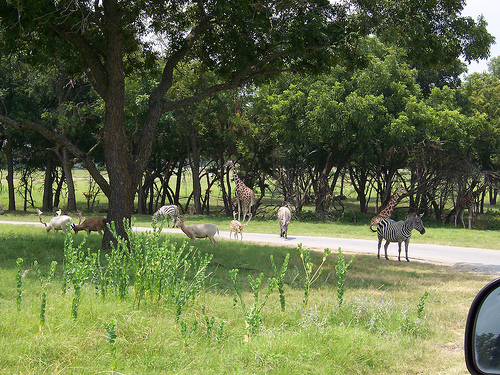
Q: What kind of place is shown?
A: It is a field.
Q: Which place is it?
A: It is a field.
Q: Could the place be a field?
A: Yes, it is a field.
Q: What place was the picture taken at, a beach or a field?
A: It was taken at a field.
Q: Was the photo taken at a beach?
A: No, the picture was taken in a field.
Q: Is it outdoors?
A: Yes, it is outdoors.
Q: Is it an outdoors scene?
A: Yes, it is outdoors.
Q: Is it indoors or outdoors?
A: It is outdoors.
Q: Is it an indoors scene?
A: No, it is outdoors.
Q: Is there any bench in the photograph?
A: No, there are no benches.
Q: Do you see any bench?
A: No, there are no benches.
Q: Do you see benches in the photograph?
A: No, there are no benches.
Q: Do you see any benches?
A: No, there are no benches.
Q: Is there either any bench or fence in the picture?
A: No, there are no benches or fences.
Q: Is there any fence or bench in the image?
A: No, there are no benches or fences.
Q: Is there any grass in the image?
A: Yes, there is grass.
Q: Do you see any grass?
A: Yes, there is grass.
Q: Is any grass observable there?
A: Yes, there is grass.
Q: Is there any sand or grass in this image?
A: Yes, there is grass.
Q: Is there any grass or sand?
A: Yes, there is grass.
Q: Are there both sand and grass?
A: No, there is grass but no sand.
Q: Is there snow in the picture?
A: No, there is no snow.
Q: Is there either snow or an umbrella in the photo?
A: No, there are no snow or umbrellas.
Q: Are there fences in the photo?
A: No, there are no fences.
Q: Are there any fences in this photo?
A: No, there are no fences.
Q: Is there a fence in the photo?
A: No, there are no fences.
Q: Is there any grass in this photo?
A: Yes, there is grass.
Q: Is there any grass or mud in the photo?
A: Yes, there is grass.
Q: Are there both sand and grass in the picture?
A: No, there is grass but no sand.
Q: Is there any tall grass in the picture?
A: Yes, there is tall grass.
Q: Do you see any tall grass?
A: Yes, there is tall grass.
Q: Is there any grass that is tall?
A: Yes, there is grass that is tall.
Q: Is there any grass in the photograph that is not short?
A: Yes, there is tall grass.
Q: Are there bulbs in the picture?
A: No, there are no bulbs.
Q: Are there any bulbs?
A: No, there are no bulbs.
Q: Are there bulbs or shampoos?
A: No, there are no bulbs or shampoos.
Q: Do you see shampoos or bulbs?
A: No, there are no bulbs or shampoos.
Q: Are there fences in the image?
A: No, there are no fences.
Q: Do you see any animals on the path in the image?
A: Yes, there is an animal on the path.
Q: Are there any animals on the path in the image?
A: Yes, there is an animal on the path.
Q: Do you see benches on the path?
A: No, there is an animal on the path.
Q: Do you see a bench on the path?
A: No, there is an animal on the path.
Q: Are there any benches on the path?
A: No, there is an animal on the path.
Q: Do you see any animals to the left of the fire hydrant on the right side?
A: Yes, there is an animal to the left of the fire hydrant.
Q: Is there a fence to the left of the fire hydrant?
A: No, there is an animal to the left of the fire hydrant.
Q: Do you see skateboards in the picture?
A: No, there are no skateboards.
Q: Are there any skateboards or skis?
A: No, there are no skateboards or skis.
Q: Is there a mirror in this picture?
A: Yes, there is a mirror.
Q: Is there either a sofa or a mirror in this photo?
A: Yes, there is a mirror.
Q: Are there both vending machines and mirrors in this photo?
A: No, there is a mirror but no vending machines.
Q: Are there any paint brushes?
A: No, there are no paint brushes.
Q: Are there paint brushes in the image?
A: No, there are no paint brushes.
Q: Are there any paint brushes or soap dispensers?
A: No, there are no paint brushes or soap dispensers.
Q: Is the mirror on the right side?
A: Yes, the mirror is on the right of the image.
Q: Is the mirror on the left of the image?
A: No, the mirror is on the right of the image.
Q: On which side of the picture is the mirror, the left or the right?
A: The mirror is on the right of the image.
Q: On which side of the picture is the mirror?
A: The mirror is on the right of the image.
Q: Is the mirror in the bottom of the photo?
A: Yes, the mirror is in the bottom of the image.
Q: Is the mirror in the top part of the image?
A: No, the mirror is in the bottom of the image.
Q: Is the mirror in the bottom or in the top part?
A: The mirror is in the bottom of the image.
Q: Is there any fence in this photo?
A: No, there are no fences.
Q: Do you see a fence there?
A: No, there are no fences.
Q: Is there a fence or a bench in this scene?
A: No, there are no fences or benches.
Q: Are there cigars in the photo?
A: No, there are no cigars.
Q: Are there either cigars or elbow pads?
A: No, there are no cigars or elbow pads.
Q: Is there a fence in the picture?
A: No, there are no fences.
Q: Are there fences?
A: No, there are no fences.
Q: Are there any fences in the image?
A: No, there are no fences.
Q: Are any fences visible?
A: No, there are no fences.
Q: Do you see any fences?
A: No, there are no fences.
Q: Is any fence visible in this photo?
A: No, there are no fences.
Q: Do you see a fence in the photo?
A: No, there are no fences.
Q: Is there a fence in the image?
A: No, there are no fences.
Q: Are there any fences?
A: No, there are no fences.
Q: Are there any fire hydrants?
A: Yes, there is a fire hydrant.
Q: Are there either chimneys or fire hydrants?
A: Yes, there is a fire hydrant.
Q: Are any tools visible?
A: No, there are no tools.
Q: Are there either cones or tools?
A: No, there are no tools or cones.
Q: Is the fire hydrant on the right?
A: Yes, the fire hydrant is on the right of the image.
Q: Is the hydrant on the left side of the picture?
A: No, the hydrant is on the right of the image.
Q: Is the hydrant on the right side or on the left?
A: The hydrant is on the right of the image.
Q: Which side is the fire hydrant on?
A: The fire hydrant is on the right of the image.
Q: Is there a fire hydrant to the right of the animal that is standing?
A: Yes, there is a fire hydrant to the right of the animal.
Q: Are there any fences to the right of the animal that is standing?
A: No, there is a fire hydrant to the right of the animal.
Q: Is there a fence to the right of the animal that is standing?
A: No, there is a fire hydrant to the right of the animal.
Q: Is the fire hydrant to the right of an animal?
A: Yes, the fire hydrant is to the right of an animal.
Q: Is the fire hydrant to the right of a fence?
A: No, the fire hydrant is to the right of an animal.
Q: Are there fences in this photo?
A: No, there are no fences.